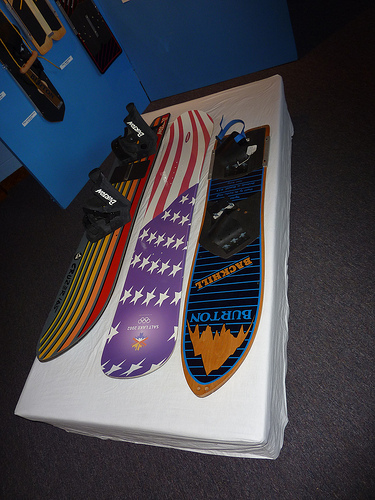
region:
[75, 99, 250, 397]
Three snowboards on the table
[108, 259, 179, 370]
Purple and white surfboard with stars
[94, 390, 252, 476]
The table has a white cloth on it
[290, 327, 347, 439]
The carpet is dark colored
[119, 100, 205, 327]
The snowboard is like the american flag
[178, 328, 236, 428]
The snowboard is pointed in the front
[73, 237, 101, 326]
Snowboard has stripes on it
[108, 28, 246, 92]
The wall is painted blue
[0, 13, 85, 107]
Snowboards hanging on the wall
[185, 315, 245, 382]
Mountain decal on the snowboard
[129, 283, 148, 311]
this board has stars on it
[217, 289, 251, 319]
this snowboard is black and blue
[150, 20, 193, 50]
the wall is blue in color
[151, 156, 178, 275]
this board is red white and blue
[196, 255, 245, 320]
the word is orange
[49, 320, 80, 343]
this board has yellow orange and red lines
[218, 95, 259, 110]
the cloth is white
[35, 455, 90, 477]
the carpet is gray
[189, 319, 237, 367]
the mountain design is orange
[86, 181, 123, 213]
this word is white in color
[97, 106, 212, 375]
American flag on snowboard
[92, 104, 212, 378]
American flag snowboard next to snowboard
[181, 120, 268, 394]
Snowboard on table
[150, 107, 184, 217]
Red stripe on snowboard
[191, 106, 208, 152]
Red stripe on snowboard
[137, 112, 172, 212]
Red stripe on snowboard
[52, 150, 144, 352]
Orange stripe on snowboard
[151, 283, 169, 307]
White star on snowboard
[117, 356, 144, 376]
White star on snowboard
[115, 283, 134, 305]
White star on snowboard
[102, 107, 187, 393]
snowboard with an American flag design on it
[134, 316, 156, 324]
small white Olympics symbol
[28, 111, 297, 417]
three snowboards laying next to each other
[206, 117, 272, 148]
blue foot strap on the board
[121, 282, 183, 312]
row of white stars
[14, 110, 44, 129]
black writing on a white background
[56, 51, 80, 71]
small sign on the wall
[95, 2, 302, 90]
dark blue wall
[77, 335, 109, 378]
small wrinkles in the fabric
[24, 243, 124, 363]
stripes on the baord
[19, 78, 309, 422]
snowboards that are on display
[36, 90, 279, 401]
three snowboards on display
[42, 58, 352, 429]
three snow boards layin down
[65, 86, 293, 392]
three snowboards next to each other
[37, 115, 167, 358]
a striped snowboard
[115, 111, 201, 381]
a red white blue snowboard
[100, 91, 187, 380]
a snowboard with american flag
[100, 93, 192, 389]
a snowboard with flag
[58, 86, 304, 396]
a snowboard on white table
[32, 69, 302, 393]
snowboards on white table